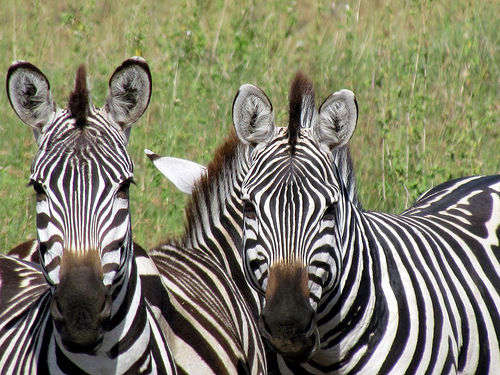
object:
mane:
[284, 62, 320, 152]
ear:
[231, 80, 275, 147]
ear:
[317, 87, 360, 150]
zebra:
[228, 69, 498, 373]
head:
[228, 76, 371, 363]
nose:
[257, 267, 318, 337]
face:
[233, 132, 342, 365]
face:
[30, 107, 130, 349]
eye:
[115, 177, 134, 201]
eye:
[28, 176, 53, 206]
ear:
[4, 58, 52, 132]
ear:
[101, 54, 154, 125]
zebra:
[0, 56, 265, 375]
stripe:
[353, 212, 407, 372]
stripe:
[361, 206, 437, 373]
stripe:
[133, 257, 263, 373]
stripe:
[426, 186, 498, 286]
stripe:
[299, 206, 379, 320]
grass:
[1, 6, 499, 267]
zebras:
[143, 128, 258, 375]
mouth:
[255, 322, 331, 365]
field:
[353, 75, 445, 135]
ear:
[230, 82, 275, 155]